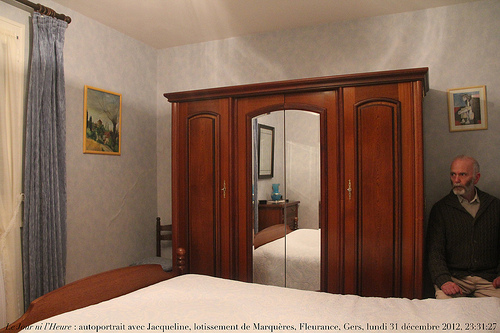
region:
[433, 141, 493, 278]
MAN IS seated beside the door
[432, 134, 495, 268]
man is looking in one direction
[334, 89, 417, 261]
the wardrobe uis made of wood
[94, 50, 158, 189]
a picture frame is on the wall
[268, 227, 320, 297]
bed is reflectd throughh the mirror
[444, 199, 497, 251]
sweater is black incolor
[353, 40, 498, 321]
a man is sitting in a bedroom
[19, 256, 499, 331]
the bedstead is wooden in the bedroom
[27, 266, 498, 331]
a white bedspread is on the bed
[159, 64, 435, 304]
a mirror is in the center of the closet cupboard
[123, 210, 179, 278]
a ladder back chair is in the corner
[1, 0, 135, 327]
a framed painting is on the wall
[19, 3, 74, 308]
the curtains are blue in the bedroom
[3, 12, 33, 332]
a window has white curtains on it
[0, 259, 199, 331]
Brown foot board on bed.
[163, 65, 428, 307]
Brown wardrobe in room.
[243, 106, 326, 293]
Mirror on front of wardrobe.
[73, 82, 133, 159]
Picture hanging on wall.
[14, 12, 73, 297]
Gray blue curtain hanging at window.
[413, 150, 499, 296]
Man sitting next to wardrobe.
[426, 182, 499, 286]
Man dressed in brown sweater.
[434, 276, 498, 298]
Man dressed in tan pants.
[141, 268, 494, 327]
White bedspread on bed.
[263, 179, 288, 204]
Reflection of blue vase in wardrobe mirror.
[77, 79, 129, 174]
a picture hanging on a wall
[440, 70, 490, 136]
a framed picture hanging on a wall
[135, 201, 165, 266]
a wood chair with a cushion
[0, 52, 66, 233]
blue and white curtains hanging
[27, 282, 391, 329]
a bed with a white cover on it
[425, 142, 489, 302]
a man sitting in a chair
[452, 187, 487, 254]
a man wearing a black sweater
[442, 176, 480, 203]
a man with facial hair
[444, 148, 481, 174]
a man with a receding hair line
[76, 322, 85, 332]
black print style letter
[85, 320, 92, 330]
black print style letter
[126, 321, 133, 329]
black print style letter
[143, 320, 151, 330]
black print style letter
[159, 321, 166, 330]
black print style letter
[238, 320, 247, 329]
black print style letter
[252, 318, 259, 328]
black print style letter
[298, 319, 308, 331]
black print style letter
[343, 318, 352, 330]
black print style letter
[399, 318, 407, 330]
black print style letter